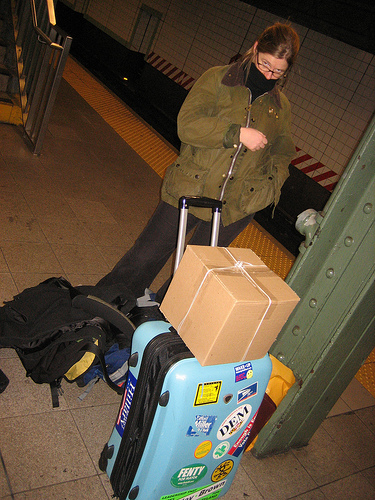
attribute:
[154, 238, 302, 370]
box — cardboard, sealed, wrapped, tied, brown, big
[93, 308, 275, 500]
luggage — light blue, big, blue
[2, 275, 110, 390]
bags — blue, black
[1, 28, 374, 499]
ground — dingy, dark grey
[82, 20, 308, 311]
woman — waiting, looking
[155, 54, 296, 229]
jacket — green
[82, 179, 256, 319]
pants — black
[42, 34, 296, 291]
area — yellow, caution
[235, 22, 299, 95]
hair — brown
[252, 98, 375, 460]
beam — green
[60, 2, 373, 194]
wall — white, tiled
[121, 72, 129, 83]
light — small